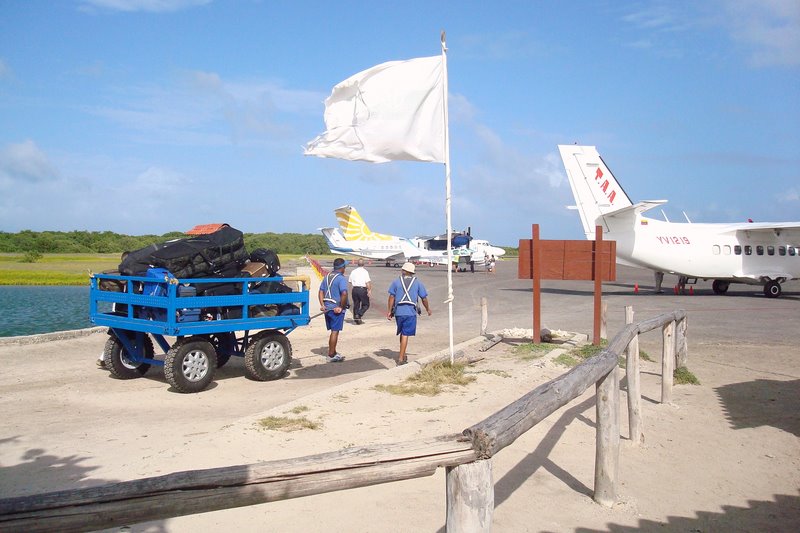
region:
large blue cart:
[89, 239, 317, 396]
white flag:
[315, 42, 465, 181]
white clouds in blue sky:
[64, 70, 121, 118]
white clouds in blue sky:
[11, 145, 81, 183]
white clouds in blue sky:
[98, 131, 216, 204]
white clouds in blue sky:
[228, 93, 285, 145]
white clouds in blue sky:
[489, 31, 580, 97]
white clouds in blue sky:
[658, 70, 722, 120]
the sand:
[647, 434, 725, 478]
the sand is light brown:
[658, 443, 750, 504]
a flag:
[321, 67, 461, 166]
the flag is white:
[326, 65, 454, 151]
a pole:
[442, 170, 474, 367]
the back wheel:
[166, 330, 226, 387]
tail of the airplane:
[554, 131, 637, 219]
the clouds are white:
[182, 72, 263, 150]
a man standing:
[386, 262, 424, 359]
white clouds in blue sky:
[197, 71, 238, 115]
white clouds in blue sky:
[36, 102, 118, 146]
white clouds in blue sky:
[132, 112, 214, 163]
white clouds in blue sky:
[694, 61, 755, 115]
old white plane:
[568, 152, 798, 314]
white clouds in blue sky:
[63, 23, 106, 82]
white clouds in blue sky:
[156, 157, 204, 193]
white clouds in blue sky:
[201, 105, 257, 165]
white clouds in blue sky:
[609, 32, 675, 92]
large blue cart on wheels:
[89, 259, 317, 388]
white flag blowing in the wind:
[309, 23, 464, 361]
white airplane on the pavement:
[548, 143, 790, 298]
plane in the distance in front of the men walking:
[323, 202, 493, 268]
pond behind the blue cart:
[8, 278, 82, 346]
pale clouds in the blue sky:
[13, 64, 263, 192]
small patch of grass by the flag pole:
[419, 351, 493, 405]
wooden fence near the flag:
[496, 315, 704, 493]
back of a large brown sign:
[512, 227, 616, 360]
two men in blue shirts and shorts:
[316, 253, 432, 355]